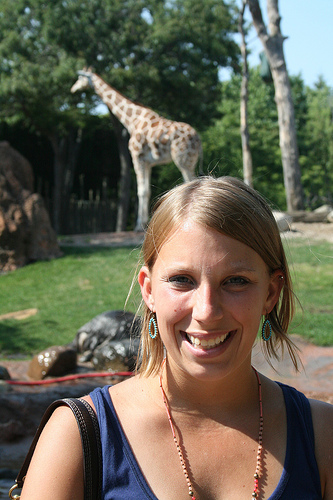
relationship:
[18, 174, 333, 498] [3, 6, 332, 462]
girl at zoo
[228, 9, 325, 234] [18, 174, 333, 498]
trees behind girl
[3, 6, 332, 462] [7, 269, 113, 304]
zoo has grass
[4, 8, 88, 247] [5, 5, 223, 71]
trees have leaves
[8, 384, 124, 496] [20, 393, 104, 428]
purse has strap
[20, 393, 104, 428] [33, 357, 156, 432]
strap on shoulder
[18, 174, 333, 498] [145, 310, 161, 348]
girl wearing earrings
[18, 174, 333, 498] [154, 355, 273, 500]
girl wearing necklace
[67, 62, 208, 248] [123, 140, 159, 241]
giraffe has legs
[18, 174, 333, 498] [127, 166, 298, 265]
girl has hair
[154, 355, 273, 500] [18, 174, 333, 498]
necklace on girl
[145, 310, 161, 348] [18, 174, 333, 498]
earrings are on girl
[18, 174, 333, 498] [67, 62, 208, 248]
girl in front of giraffe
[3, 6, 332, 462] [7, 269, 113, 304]
enclosure has grass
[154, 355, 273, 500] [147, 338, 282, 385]
necklace around neck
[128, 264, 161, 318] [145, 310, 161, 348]
left ear has earring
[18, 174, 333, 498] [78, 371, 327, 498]
girl has tanktop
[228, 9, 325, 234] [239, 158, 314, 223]
trees have trunks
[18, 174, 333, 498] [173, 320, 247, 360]
girl has smile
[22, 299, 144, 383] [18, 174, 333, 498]
rocks are behind girl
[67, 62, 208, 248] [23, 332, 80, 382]
giraffe near rock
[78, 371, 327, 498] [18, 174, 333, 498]
shirt on girl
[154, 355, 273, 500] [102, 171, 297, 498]
necklace on girl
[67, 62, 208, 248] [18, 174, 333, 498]
giraffe behind girl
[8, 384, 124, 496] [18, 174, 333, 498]
bag on girl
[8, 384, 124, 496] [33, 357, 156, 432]
bag on shoulder